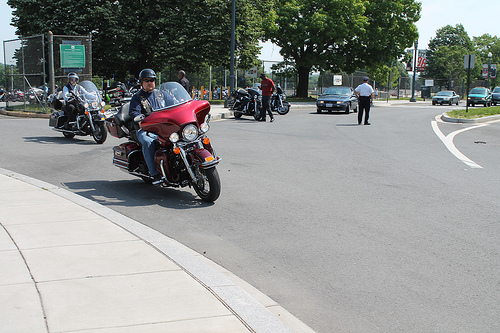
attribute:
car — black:
[431, 89, 459, 110]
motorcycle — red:
[103, 80, 222, 204]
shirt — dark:
[128, 88, 158, 132]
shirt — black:
[122, 89, 184, 126]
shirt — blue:
[351, 83, 375, 98]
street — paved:
[213, 114, 497, 329]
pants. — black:
[252, 94, 278, 123]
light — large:
[177, 122, 203, 144]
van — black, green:
[449, 73, 494, 123]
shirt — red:
[258, 77, 275, 97]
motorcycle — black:
[223, 87, 270, 126]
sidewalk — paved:
[3, 162, 311, 329]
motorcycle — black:
[90, 96, 240, 204]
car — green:
[430, 90, 461, 107]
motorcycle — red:
[89, 69, 262, 223]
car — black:
[312, 86, 353, 121]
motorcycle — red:
[114, 59, 253, 215]